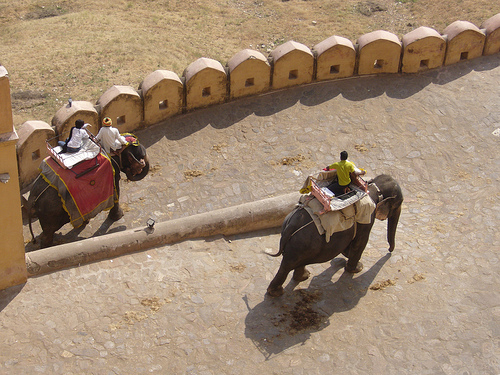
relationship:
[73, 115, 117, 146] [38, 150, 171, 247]
people on elephant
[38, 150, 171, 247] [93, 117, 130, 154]
elephant with people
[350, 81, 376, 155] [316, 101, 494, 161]
concrete on ground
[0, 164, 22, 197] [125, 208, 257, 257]
light on post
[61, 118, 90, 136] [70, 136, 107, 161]
boy has shirt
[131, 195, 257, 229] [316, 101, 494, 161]
divider in ground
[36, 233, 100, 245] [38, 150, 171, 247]
shadow os elephant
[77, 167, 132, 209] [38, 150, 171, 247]
blanket on elephant